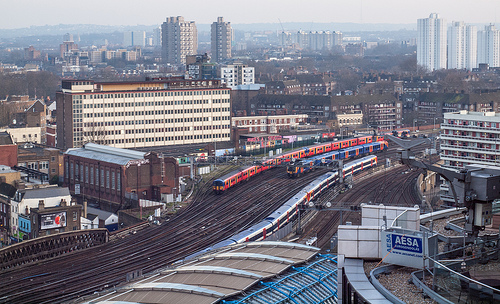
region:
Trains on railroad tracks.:
[209, 132, 384, 209]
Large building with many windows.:
[80, 81, 235, 142]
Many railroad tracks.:
[175, 194, 272, 234]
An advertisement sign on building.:
[37, 213, 69, 230]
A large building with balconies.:
[437, 110, 498, 163]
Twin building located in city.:
[218, 64, 258, 87]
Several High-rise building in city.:
[417, 8, 499, 74]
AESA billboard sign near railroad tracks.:
[382, 218, 442, 274]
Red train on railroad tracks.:
[202, 160, 274, 190]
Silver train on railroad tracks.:
[245, 163, 385, 213]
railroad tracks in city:
[197, 185, 249, 236]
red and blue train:
[219, 140, 300, 207]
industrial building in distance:
[65, 90, 152, 143]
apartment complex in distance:
[147, 17, 204, 63]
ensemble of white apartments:
[403, 26, 490, 63]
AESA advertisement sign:
[378, 228, 436, 288]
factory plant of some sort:
[65, 138, 214, 212]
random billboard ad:
[35, 205, 90, 235]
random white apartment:
[10, 180, 33, 235]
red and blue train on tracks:
[249, 125, 297, 211]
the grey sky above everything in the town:
[3, 2, 499, 24]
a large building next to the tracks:
[58, 80, 233, 147]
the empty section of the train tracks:
[7, 188, 304, 296]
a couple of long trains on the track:
[213, 120, 411, 197]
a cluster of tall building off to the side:
[416, 17, 499, 69]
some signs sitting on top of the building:
[333, 199, 425, 269]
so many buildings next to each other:
[231, 67, 498, 125]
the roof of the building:
[349, 204, 499, 297]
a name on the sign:
[381, 227, 424, 257]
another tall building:
[441, 110, 499, 180]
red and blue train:
[213, 155, 265, 198]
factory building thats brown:
[69, 138, 141, 198]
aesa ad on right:
[394, 228, 430, 263]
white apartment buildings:
[387, 5, 487, 72]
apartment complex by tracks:
[83, 90, 255, 138]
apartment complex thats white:
[7, 120, 44, 152]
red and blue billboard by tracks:
[19, 200, 97, 247]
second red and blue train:
[290, 150, 334, 185]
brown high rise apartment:
[158, 46, 227, 67]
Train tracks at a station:
[48, 184, 306, 270]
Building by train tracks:
[48, 137, 252, 229]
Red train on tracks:
[195, 104, 383, 205]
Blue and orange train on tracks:
[272, 121, 427, 187]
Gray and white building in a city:
[53, 69, 235, 173]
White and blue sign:
[375, 223, 445, 273]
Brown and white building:
[228, 106, 326, 149]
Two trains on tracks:
[186, 117, 434, 222]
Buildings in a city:
[28, 40, 347, 167]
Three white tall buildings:
[411, 9, 499, 82]